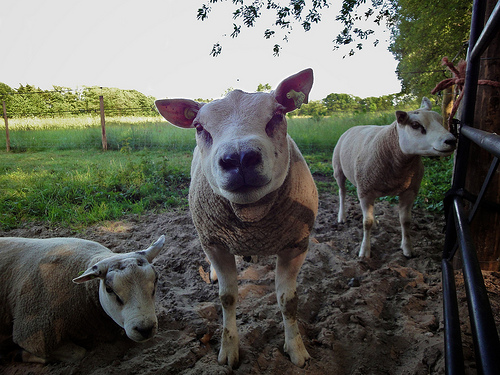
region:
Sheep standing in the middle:
[153, 67, 315, 368]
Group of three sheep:
[0, 68, 456, 369]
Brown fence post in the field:
[95, 93, 115, 148]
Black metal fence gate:
[443, 1, 498, 373]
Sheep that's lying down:
[0, 231, 165, 362]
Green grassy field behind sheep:
[0, 105, 465, 230]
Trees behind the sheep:
[0, 85, 448, 119]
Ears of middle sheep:
[154, 68, 315, 128]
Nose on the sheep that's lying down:
[131, 318, 159, 340]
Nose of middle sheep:
[217, 148, 270, 175]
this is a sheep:
[0, 232, 187, 374]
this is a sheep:
[151, 53, 327, 367]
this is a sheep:
[327, 96, 464, 263]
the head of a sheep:
[72, 228, 179, 348]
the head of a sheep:
[142, 63, 323, 208]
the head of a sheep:
[386, 90, 461, 175]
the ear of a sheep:
[65, 259, 105, 290]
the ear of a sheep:
[142, 228, 170, 257]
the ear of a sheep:
[259, 53, 331, 128]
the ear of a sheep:
[142, 92, 203, 148]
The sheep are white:
[6, 61, 453, 353]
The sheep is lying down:
[8, 220, 183, 355]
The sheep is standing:
[153, 66, 328, 359]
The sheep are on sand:
[6, 67, 456, 367]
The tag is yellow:
[283, 84, 316, 110]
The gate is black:
[431, 3, 497, 363]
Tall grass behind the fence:
[0, 106, 420, 154]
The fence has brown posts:
[0, 97, 173, 155]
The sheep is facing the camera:
[146, 54, 334, 364]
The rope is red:
[428, 56, 496, 98]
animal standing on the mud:
[117, 61, 365, 373]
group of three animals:
[1, 66, 461, 373]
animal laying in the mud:
[2, 228, 175, 365]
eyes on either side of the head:
[187, 109, 292, 141]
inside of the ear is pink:
[154, 96, 199, 131]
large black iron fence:
[411, 1, 498, 374]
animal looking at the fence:
[312, 90, 487, 277]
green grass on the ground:
[4, 140, 204, 228]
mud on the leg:
[274, 285, 304, 320]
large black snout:
[204, 138, 278, 200]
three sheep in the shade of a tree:
[0, 64, 462, 367]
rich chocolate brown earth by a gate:
[0, 182, 499, 372]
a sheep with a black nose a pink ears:
[154, 65, 322, 373]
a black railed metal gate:
[439, 1, 499, 372]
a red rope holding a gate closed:
[429, 53, 498, 128]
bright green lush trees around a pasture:
[2, 0, 476, 123]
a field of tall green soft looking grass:
[2, 109, 441, 226]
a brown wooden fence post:
[97, 91, 109, 151]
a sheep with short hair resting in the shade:
[0, 232, 170, 367]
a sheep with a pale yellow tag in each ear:
[154, 66, 321, 368]